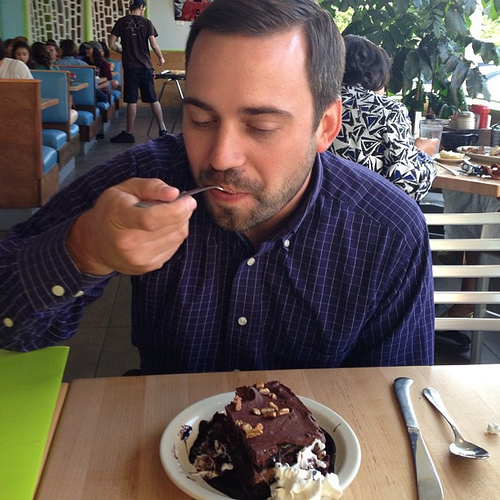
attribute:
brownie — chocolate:
[218, 375, 326, 463]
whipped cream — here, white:
[289, 469, 329, 485]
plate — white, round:
[163, 393, 214, 419]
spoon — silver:
[422, 367, 479, 470]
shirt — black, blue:
[149, 262, 397, 349]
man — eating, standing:
[40, 0, 430, 355]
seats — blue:
[19, 131, 82, 157]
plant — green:
[389, 4, 460, 90]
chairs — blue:
[96, 93, 113, 111]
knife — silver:
[386, 387, 439, 497]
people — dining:
[1, 20, 131, 107]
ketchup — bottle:
[462, 79, 485, 126]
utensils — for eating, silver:
[396, 376, 484, 490]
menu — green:
[1, 393, 36, 442]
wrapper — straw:
[438, 156, 463, 175]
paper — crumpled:
[419, 140, 448, 175]